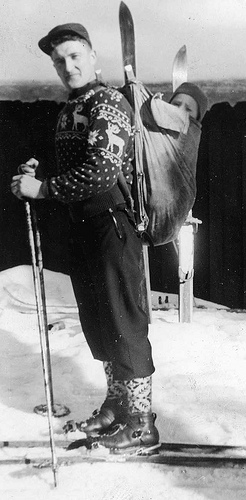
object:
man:
[11, 23, 160, 455]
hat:
[37, 22, 93, 57]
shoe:
[100, 413, 159, 448]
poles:
[23, 198, 56, 487]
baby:
[167, 79, 207, 122]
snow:
[1, 264, 244, 497]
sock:
[125, 377, 154, 413]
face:
[54, 50, 87, 90]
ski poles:
[32, 199, 56, 407]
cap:
[168, 81, 207, 124]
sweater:
[46, 83, 134, 215]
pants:
[68, 210, 156, 381]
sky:
[2, 1, 242, 79]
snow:
[2, 307, 246, 500]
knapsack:
[121, 65, 200, 249]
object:
[176, 207, 203, 322]